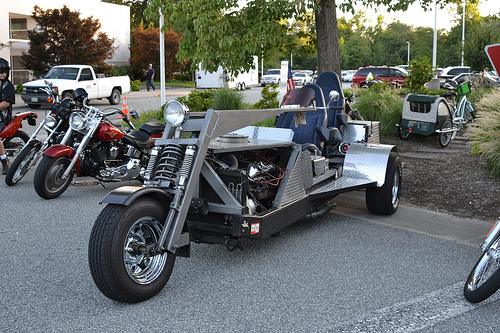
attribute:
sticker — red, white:
[247, 213, 272, 249]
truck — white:
[20, 62, 131, 108]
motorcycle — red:
[34, 95, 159, 210]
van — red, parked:
[346, 63, 412, 90]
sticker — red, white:
[338, 60, 418, 92]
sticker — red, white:
[67, 65, 103, 91]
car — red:
[298, 49, 439, 120]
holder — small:
[391, 92, 458, 146]